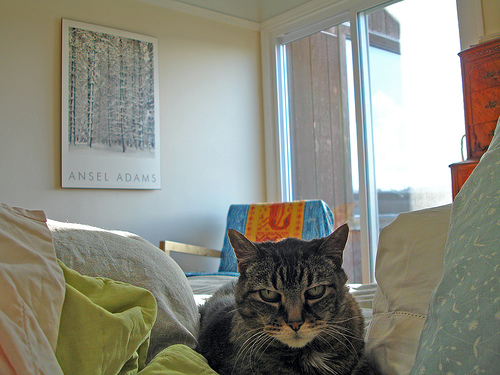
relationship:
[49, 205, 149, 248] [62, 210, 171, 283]
sunlight shining on blanket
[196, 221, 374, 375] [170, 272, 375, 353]
cat laying on bed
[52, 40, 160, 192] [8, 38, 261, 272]
print attached to wall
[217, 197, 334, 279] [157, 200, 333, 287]
fabric on chair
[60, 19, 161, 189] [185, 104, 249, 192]
poster on wall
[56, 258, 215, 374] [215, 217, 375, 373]
blanket next to cat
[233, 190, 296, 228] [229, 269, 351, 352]
chair behind cat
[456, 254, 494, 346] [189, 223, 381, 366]
blanket next to cat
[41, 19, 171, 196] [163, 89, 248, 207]
poster on wall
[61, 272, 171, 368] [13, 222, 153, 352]
blanket on bed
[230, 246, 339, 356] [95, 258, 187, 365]
cat on bed